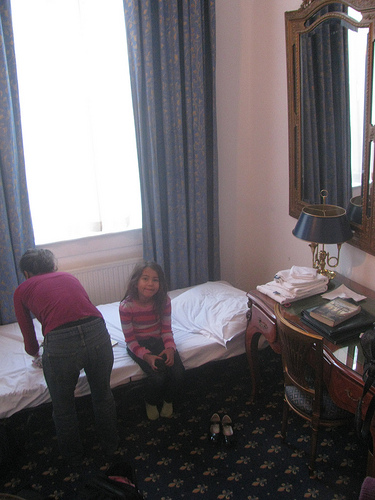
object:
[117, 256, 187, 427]
girl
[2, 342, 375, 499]
floor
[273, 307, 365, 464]
chair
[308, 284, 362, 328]
book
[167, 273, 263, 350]
pillow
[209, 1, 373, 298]
wall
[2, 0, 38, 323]
curtain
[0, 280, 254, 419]
sheets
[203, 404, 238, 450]
shoes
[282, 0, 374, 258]
mirror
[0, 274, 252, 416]
bed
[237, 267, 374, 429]
desk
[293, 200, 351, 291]
lamp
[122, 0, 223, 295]
curtains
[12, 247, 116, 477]
woman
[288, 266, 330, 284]
towels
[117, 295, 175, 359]
shirt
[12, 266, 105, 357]
shirt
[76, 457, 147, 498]
bag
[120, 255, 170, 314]
hair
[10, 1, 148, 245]
light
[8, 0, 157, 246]
window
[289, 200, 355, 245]
shade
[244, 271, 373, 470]
wood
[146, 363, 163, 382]
knees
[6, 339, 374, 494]
mat